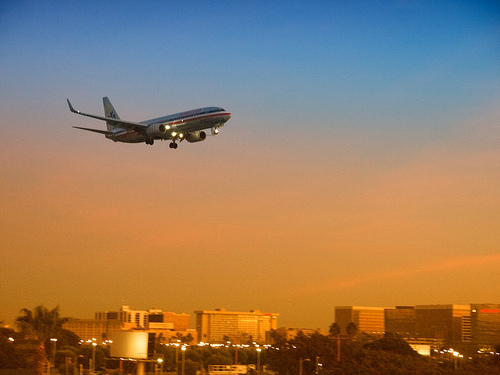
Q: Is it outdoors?
A: Yes, it is outdoors.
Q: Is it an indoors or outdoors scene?
A: It is outdoors.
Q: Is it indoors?
A: No, it is outdoors.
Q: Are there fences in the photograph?
A: No, there are no fences.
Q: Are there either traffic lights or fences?
A: No, there are no fences or traffic lights.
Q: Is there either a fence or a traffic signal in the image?
A: No, there are no fences or traffic lights.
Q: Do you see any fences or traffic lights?
A: No, there are no fences or traffic lights.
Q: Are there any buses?
A: No, there are no buses.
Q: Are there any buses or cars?
A: No, there are no buses or cars.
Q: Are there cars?
A: No, there are no cars.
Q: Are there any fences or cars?
A: No, there are no cars or fences.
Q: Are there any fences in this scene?
A: No, there are no fences.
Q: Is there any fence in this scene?
A: No, there are no fences.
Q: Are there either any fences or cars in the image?
A: No, there are no fences or cars.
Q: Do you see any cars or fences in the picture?
A: No, there are no fences or cars.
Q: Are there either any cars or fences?
A: No, there are no fences or cars.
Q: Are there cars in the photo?
A: No, there are no cars.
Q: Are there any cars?
A: No, there are no cars.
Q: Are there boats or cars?
A: No, there are no cars or boats.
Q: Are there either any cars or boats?
A: No, there are no cars or boats.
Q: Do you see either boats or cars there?
A: No, there are no cars or boats.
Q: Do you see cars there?
A: No, there are no cars.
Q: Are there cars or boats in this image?
A: No, there are no cars or boats.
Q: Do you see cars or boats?
A: No, there are no cars or boats.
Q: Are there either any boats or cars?
A: No, there are no cars or boats.